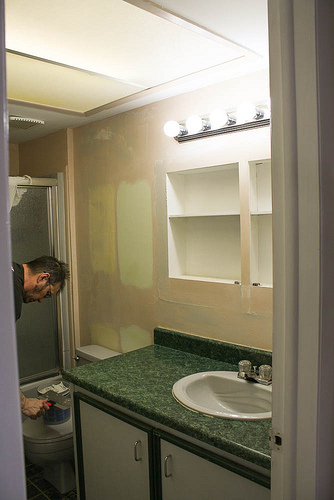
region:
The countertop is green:
[91, 308, 269, 458]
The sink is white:
[183, 354, 277, 454]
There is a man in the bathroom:
[24, 235, 105, 363]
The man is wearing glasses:
[15, 242, 73, 342]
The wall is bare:
[84, 176, 151, 310]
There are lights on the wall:
[156, 104, 287, 172]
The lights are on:
[157, 104, 275, 178]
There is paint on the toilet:
[21, 370, 88, 466]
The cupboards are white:
[79, 402, 210, 498]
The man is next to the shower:
[9, 174, 92, 366]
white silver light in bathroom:
[155, 120, 190, 150]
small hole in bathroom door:
[266, 431, 289, 453]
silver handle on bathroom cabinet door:
[157, 446, 178, 485]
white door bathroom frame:
[273, 272, 333, 395]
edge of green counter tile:
[58, 368, 115, 399]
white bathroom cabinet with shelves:
[158, 156, 289, 309]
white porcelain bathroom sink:
[172, 365, 282, 428]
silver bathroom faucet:
[229, 357, 276, 385]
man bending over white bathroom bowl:
[9, 256, 79, 408]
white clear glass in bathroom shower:
[14, 169, 92, 381]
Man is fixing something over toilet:
[11, 216, 86, 496]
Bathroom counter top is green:
[64, 308, 278, 472]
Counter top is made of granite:
[77, 325, 274, 462]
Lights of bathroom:
[150, 94, 258, 136]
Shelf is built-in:
[151, 148, 261, 278]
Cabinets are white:
[68, 384, 252, 493]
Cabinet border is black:
[62, 386, 277, 498]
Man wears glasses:
[11, 252, 65, 431]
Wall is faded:
[68, 112, 151, 339]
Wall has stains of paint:
[83, 176, 162, 294]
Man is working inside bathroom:
[2, 230, 87, 433]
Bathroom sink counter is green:
[87, 317, 285, 455]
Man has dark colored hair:
[12, 245, 75, 326]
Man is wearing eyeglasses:
[7, 242, 79, 321]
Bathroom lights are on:
[162, 108, 286, 146]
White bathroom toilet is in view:
[21, 335, 133, 496]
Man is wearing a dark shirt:
[10, 253, 47, 354]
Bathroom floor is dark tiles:
[23, 460, 96, 498]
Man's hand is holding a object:
[26, 390, 62, 422]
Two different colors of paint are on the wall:
[82, 176, 173, 293]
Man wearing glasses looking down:
[10, 254, 77, 318]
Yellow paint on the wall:
[81, 185, 114, 274]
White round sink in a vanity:
[173, 356, 271, 425]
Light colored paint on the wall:
[118, 183, 154, 286]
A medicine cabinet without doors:
[164, 153, 272, 285]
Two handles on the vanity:
[130, 437, 186, 480]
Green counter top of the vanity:
[58, 345, 172, 411]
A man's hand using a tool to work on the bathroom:
[22, 378, 74, 422]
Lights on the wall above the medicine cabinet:
[160, 105, 268, 143]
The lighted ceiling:
[6, 2, 269, 115]